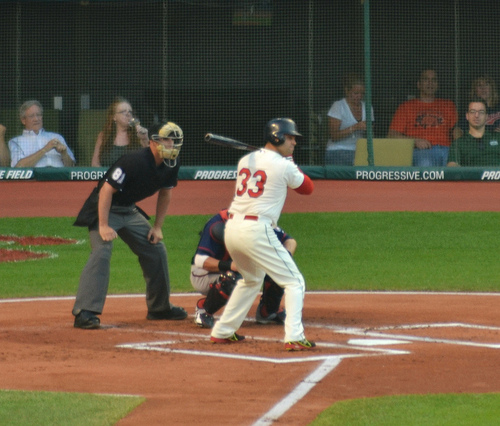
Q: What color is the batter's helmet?
A: Black.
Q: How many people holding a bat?
A: One.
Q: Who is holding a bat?
A: A man.